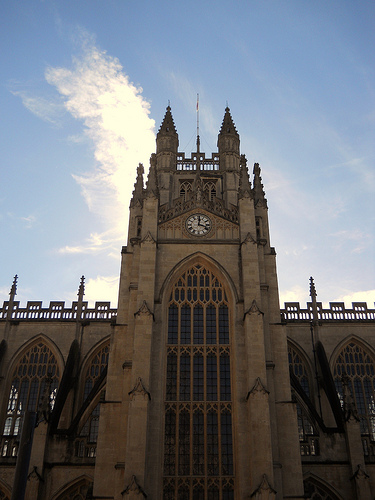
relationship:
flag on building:
[190, 90, 209, 112] [88, 88, 313, 499]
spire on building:
[307, 268, 330, 308] [88, 88, 313, 499]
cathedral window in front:
[156, 248, 239, 497] [1, 90, 374, 500]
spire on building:
[193, 110, 209, 150] [88, 88, 313, 499]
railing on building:
[4, 295, 120, 323] [88, 88, 313, 499]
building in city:
[88, 88, 313, 499] [1, 0, 374, 500]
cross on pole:
[80, 273, 88, 281] [78, 281, 86, 320]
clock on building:
[185, 209, 216, 243] [88, 88, 313, 499]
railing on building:
[47, 340, 77, 454] [88, 88, 313, 499]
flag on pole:
[190, 90, 209, 112] [193, 110, 209, 150]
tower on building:
[108, 85, 294, 323] [88, 88, 313, 499]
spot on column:
[246, 262, 261, 285] [245, 152, 275, 499]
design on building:
[8, 96, 374, 493] [88, 88, 313, 499]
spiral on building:
[214, 98, 250, 140] [88, 88, 313, 499]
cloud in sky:
[32, 40, 152, 148] [0, 1, 375, 304]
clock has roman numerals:
[185, 209, 216, 243] [205, 222, 213, 227]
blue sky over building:
[0, 1, 375, 304] [88, 88, 313, 499]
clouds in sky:
[32, 40, 152, 148] [0, 1, 375, 304]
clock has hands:
[185, 209, 216, 243] [197, 221, 205, 222]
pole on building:
[78, 281, 86, 320] [88, 88, 313, 499]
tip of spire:
[167, 97, 175, 107] [154, 105, 182, 142]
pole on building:
[193, 110, 209, 150] [88, 88, 313, 499]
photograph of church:
[5, 4, 374, 499] [88, 88, 313, 499]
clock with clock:
[185, 209, 216, 243] [185, 209, 216, 239]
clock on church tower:
[185, 209, 216, 243] [88, 88, 313, 499]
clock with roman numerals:
[185, 209, 216, 243] [205, 222, 213, 227]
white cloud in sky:
[32, 40, 152, 148] [0, 1, 375, 304]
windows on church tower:
[164, 172, 243, 499] [88, 88, 313, 499]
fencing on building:
[4, 295, 120, 323] [88, 88, 313, 499]